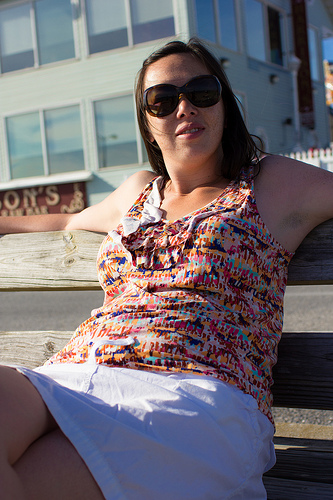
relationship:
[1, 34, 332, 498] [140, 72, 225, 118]
girl wearing sunglasses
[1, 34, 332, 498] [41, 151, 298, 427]
girl wearing tank top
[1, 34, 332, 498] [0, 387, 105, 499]
girl has thigh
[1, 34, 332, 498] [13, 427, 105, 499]
girl has thigh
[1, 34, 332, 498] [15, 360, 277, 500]
girl wearing mini-skirt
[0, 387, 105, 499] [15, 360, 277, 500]
thigh under mini-skirt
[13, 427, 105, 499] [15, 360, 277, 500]
thigh under mini-skirt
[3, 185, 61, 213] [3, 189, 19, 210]
letter has letter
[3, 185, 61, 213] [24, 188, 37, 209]
letter has letter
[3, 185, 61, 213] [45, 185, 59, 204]
letter has letter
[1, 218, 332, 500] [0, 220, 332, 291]
bench has slat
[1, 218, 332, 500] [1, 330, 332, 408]
bench has slat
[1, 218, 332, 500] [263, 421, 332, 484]
bench has slat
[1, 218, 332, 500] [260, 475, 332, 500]
bench has slat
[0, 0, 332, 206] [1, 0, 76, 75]
building has window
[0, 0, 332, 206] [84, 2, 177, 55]
building has window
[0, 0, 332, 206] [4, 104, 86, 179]
building has window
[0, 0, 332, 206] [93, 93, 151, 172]
building has window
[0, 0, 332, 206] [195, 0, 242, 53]
building has window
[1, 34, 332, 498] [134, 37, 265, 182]
girl has hair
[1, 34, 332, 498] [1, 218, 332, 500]
girl sitting on bench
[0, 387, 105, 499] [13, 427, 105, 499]
thigh crossed over thigh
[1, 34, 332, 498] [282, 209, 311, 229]
girl has armpit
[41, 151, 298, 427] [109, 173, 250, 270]
tank top has ruffle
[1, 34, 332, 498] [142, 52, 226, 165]
girl has face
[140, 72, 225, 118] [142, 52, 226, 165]
sunglasses on face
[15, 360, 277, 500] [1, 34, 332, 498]
mini-skirt on girl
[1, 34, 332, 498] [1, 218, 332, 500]
girl on bench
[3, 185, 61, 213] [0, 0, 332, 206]
letter on building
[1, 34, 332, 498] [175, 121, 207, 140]
girl has mouth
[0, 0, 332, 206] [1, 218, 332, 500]
building behind bench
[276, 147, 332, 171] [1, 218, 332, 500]
fence behind bench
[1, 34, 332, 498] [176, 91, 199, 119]
girl has nose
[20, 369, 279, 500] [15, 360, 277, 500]
shadow on mini-skirt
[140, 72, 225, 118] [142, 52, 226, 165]
sunglasses are on face